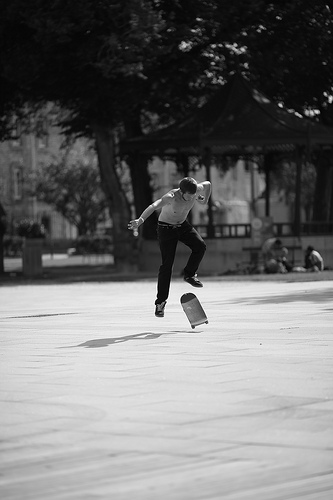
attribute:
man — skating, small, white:
[132, 166, 219, 321]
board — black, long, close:
[178, 288, 214, 336]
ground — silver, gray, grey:
[6, 267, 332, 499]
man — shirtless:
[121, 169, 210, 325]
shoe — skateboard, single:
[146, 293, 169, 322]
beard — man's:
[177, 188, 189, 204]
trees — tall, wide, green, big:
[1, 0, 322, 243]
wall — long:
[134, 227, 322, 274]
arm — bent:
[192, 175, 216, 206]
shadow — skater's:
[50, 323, 195, 354]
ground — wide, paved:
[1, 283, 321, 493]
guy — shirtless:
[124, 174, 213, 321]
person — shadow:
[98, 135, 263, 332]